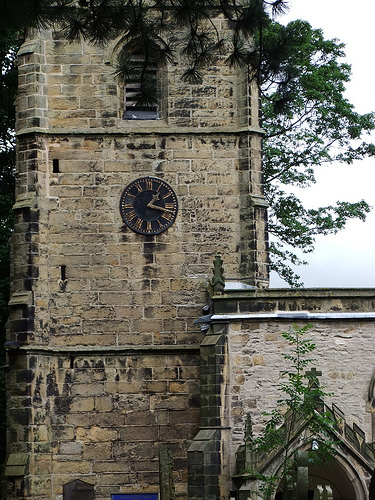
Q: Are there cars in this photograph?
A: No, there are no cars.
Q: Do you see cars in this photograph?
A: No, there are no cars.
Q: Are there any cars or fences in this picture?
A: No, there are no cars or fences.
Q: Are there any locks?
A: No, there are no locks.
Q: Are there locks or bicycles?
A: No, there are no locks or bicycles.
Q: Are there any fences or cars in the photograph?
A: No, there are no cars or fences.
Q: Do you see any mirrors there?
A: No, there are no mirrors.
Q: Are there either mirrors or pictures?
A: No, there are no mirrors or pictures.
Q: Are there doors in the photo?
A: Yes, there is a door.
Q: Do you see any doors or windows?
A: Yes, there is a door.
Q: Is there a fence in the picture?
A: No, there are no fences.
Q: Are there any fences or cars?
A: No, there are no fences or cars.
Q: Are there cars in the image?
A: No, there are no cars.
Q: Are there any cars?
A: No, there are no cars.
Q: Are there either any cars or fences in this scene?
A: No, there are no cars or fences.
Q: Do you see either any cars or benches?
A: No, there are no cars or benches.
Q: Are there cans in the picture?
A: No, there are no cans.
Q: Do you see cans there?
A: No, there are no cans.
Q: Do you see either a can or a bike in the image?
A: No, there are no cans or bikes.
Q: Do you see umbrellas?
A: No, there are no umbrellas.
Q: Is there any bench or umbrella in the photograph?
A: No, there are no umbrellas or benches.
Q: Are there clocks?
A: Yes, there is a clock.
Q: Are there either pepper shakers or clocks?
A: Yes, there is a clock.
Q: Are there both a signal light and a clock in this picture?
A: No, there is a clock but no traffic lights.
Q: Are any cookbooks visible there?
A: No, there are no cookbooks.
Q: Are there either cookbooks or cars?
A: No, there are no cookbooks or cars.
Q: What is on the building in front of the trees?
A: The clock is on the building.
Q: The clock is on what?
A: The clock is on the building.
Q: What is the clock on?
A: The clock is on the building.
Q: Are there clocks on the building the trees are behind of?
A: Yes, there is a clock on the building.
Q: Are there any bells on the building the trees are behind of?
A: No, there is a clock on the building.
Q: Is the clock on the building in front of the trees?
A: Yes, the clock is on the building.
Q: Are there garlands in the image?
A: No, there are no garlands.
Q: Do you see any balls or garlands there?
A: No, there are no garlands or balls.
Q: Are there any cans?
A: No, there are no cans.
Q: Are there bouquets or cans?
A: No, there are no cans or bouquets.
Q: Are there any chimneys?
A: No, there are no chimneys.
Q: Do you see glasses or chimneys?
A: No, there are no chimneys or glasses.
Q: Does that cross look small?
A: Yes, the cross is small.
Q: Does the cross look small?
A: Yes, the cross is small.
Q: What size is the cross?
A: The cross is small.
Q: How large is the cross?
A: The cross is small.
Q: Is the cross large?
A: No, the cross is small.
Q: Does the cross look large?
A: No, the cross is small.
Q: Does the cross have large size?
A: No, the cross is small.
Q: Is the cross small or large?
A: The cross is small.